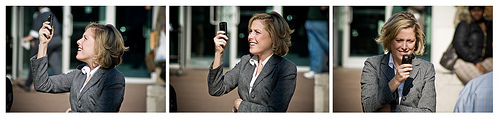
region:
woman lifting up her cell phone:
[30, 13, 140, 112]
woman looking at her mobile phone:
[201, 10, 305, 112]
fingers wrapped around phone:
[395, 49, 417, 82]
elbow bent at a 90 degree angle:
[26, 16, 83, 96]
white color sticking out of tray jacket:
[243, 55, 260, 67]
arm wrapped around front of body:
[228, 89, 292, 112]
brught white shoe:
[303, 68, 318, 78]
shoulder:
[450, 69, 499, 115]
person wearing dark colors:
[14, 8, 73, 93]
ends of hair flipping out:
[116, 40, 133, 53]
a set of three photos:
[4, 4, 496, 111]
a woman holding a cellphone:
[206, 8, 298, 111]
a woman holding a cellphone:
[361, 9, 438, 111]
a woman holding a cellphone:
[31, 7, 129, 113]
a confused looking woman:
[70, 19, 127, 70]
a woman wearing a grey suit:
[206, 11, 303, 116]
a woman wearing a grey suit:
[358, 9, 437, 110]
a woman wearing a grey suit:
[30, 13, 129, 106]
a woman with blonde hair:
[372, 12, 428, 66]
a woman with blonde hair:
[67, 18, 129, 68]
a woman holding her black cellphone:
[29, 13, 127, 108]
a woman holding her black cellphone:
[205, 13, 295, 110]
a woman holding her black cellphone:
[360, 12, 432, 105]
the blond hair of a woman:
[87, 22, 124, 66]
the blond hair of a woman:
[243, 13, 292, 55]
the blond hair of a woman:
[378, 12, 425, 57]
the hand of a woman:
[37, 21, 55, 45]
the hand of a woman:
[211, 30, 229, 53]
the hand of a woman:
[397, 63, 412, 80]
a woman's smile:
[250, 37, 257, 47]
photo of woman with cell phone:
[7, 6, 494, 111]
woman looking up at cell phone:
[12, 6, 143, 82]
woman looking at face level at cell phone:
[204, 18, 299, 96]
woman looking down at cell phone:
[369, 18, 459, 98]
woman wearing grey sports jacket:
[48, 33, 135, 100]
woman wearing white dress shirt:
[57, 5, 131, 97]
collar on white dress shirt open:
[73, 19, 120, 93]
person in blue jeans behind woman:
[294, 15, 334, 69]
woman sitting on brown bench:
[10, 66, 163, 116]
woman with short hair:
[231, 6, 299, 63]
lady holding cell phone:
[26, 10, 147, 110]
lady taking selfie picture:
[25, 23, 127, 107]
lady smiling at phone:
[201, 10, 326, 117]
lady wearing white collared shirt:
[198, 12, 357, 116]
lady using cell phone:
[357, 11, 457, 106]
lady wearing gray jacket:
[202, 19, 304, 113]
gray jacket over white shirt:
[199, 22, 321, 117]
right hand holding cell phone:
[30, 17, 136, 101]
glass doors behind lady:
[338, 9, 450, 84]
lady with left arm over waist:
[199, 14, 343, 116]